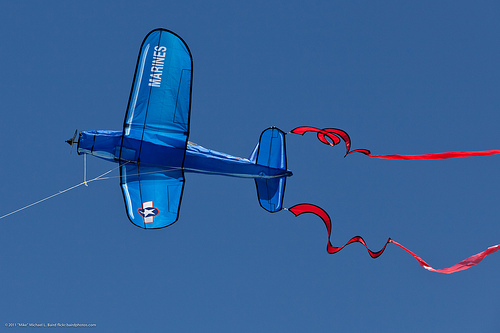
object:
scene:
[2, 0, 499, 333]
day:
[0, 0, 499, 333]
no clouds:
[3, 0, 496, 333]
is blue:
[3, 4, 498, 332]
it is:
[8, 5, 495, 326]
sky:
[0, 0, 499, 333]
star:
[139, 209, 156, 218]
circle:
[137, 207, 160, 218]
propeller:
[63, 128, 79, 155]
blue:
[7, 8, 496, 28]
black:
[178, 207, 180, 216]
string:
[0, 152, 181, 221]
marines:
[147, 45, 167, 88]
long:
[286, 120, 500, 275]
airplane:
[62, 27, 499, 276]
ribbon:
[283, 125, 499, 275]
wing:
[253, 126, 295, 214]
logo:
[137, 200, 161, 223]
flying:
[62, 27, 499, 276]